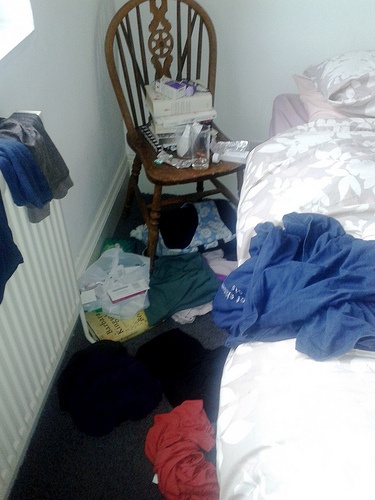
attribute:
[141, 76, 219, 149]
books — stack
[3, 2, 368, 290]
wall — white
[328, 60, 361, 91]
pattern — white and grey, floral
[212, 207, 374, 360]
shirt — navy blue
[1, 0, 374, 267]
wall — white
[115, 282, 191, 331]
book — hard cover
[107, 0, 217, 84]
brown chair — small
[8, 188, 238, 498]
floor — dark color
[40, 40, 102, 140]
wall — white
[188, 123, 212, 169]
glass — empty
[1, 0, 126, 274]
wall — white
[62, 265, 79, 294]
part — small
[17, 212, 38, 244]
part — small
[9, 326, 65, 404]
part — small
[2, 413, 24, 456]
part — small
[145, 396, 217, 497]
shirt — red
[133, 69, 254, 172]
stuff — stacked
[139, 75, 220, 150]
stack — book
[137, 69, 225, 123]
cover — hard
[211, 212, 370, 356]
clothing — blue, article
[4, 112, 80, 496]
heater — wall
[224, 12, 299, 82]
area — white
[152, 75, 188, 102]
box — medicine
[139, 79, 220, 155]
books — pile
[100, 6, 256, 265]
chair — wooden, brown